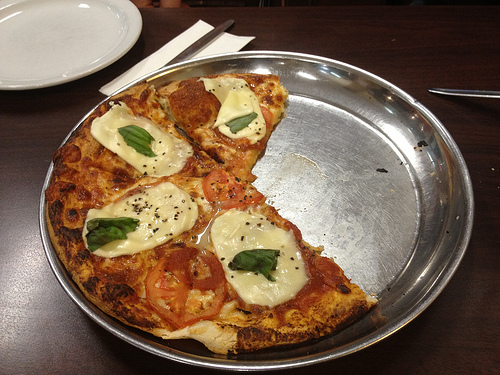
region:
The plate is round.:
[37, 48, 474, 372]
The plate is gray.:
[37, 48, 473, 371]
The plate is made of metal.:
[37, 50, 474, 370]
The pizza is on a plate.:
[35, 50, 472, 368]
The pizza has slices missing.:
[38, 50, 475, 370]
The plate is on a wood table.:
[1, 8, 498, 374]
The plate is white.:
[0, 0, 142, 91]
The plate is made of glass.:
[0, 0, 144, 88]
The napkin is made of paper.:
[97, 18, 258, 96]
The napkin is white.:
[98, 17, 253, 95]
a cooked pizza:
[40, 67, 378, 359]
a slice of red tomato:
[142, 245, 228, 327]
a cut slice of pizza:
[157, 68, 290, 178]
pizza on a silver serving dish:
[38, 50, 474, 373]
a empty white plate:
[0, 0, 144, 94]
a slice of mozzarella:
[211, 205, 309, 307]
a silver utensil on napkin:
[156, 15, 236, 70]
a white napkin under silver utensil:
[95, 15, 255, 95]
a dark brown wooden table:
[0, 3, 498, 373]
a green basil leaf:
[225, 245, 284, 283]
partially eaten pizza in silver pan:
[56, 64, 368, 345]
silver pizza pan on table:
[40, 47, 490, 347]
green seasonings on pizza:
[80, 110, 290, 284]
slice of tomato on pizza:
[136, 243, 234, 320]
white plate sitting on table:
[3, 1, 149, 98]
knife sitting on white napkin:
[147, 8, 245, 58]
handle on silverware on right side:
[427, 78, 496, 108]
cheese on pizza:
[61, 86, 317, 313]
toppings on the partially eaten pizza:
[86, 73, 331, 315]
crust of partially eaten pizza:
[37, 70, 349, 342]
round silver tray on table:
[36, 50, 474, 370]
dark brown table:
[0, 10, 495, 370]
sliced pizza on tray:
[41, 70, 376, 352]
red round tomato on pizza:
[145, 245, 221, 326]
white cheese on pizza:
[211, 205, 308, 302]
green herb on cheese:
[225, 246, 280, 281]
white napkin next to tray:
[97, 16, 252, 96]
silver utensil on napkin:
[160, 12, 235, 67]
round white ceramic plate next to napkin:
[0, 0, 140, 87]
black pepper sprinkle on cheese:
[237, 231, 243, 241]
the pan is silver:
[325, 146, 395, 196]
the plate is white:
[2, 0, 136, 80]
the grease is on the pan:
[280, 155, 324, 196]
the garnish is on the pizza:
[222, 245, 292, 274]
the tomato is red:
[143, 237, 225, 329]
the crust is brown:
[262, 315, 307, 342]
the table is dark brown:
[5, 297, 61, 365]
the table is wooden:
[447, 303, 488, 360]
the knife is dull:
[427, 73, 491, 108]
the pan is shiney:
[367, 102, 420, 143]